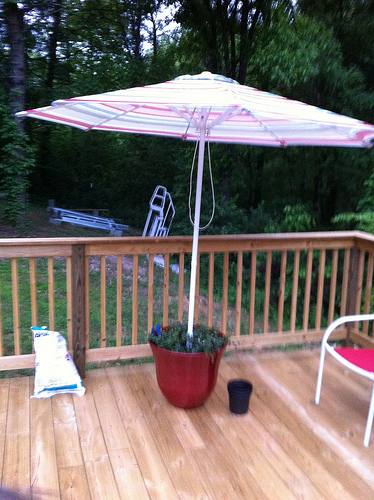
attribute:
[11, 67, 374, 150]
umbrella — pink, white, open, large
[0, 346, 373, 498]
deck — wood, wooden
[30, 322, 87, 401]
bag — white, full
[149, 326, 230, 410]
planter — red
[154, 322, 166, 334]
flower — blue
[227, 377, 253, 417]
pot — black, empty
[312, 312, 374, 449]
chair — white, red, metallic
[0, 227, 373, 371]
railing — wood, wooden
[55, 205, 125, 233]
pole — white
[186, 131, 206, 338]
post — white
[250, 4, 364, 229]
tree — green, behind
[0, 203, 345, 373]
ground — sloping, grassy, green